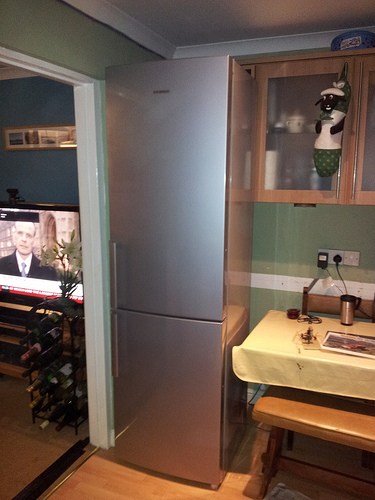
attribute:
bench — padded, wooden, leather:
[251, 374, 373, 481]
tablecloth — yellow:
[245, 287, 370, 395]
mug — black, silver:
[334, 290, 362, 342]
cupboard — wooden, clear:
[239, 63, 375, 211]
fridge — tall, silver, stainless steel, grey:
[116, 69, 237, 474]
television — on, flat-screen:
[0, 205, 98, 303]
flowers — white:
[41, 247, 96, 316]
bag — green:
[302, 78, 354, 181]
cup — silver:
[340, 296, 357, 321]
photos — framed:
[7, 124, 79, 157]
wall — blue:
[1, 86, 72, 200]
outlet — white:
[318, 250, 357, 269]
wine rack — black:
[22, 295, 89, 428]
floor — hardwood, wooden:
[62, 448, 227, 499]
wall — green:
[242, 198, 367, 277]